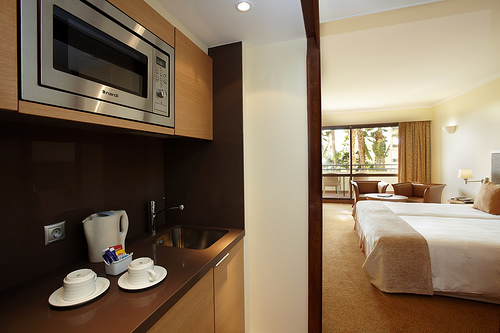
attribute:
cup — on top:
[128, 256, 154, 284]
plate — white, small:
[116, 263, 167, 290]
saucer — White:
[47, 275, 111, 307]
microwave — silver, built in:
[18, 1, 176, 131]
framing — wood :
[297, 20, 334, 331]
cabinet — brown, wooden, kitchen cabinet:
[173, 35, 213, 141]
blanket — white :
[400, 215, 499, 292]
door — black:
[38, 6, 151, 111]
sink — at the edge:
[155, 223, 232, 249]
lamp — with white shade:
[459, 167, 490, 184]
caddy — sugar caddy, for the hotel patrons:
[95, 243, 142, 280]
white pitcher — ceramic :
[81, 209, 125, 262]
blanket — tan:
[356, 198, 494, 290]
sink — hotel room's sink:
[145, 189, 232, 266]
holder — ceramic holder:
[101, 244, 133, 276]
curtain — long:
[394, 120, 431, 177]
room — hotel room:
[53, 18, 480, 310]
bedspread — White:
[388, 201, 498, 298]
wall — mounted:
[414, 122, 499, 218]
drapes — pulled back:
[345, 120, 457, 202]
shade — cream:
[432, 154, 474, 204]